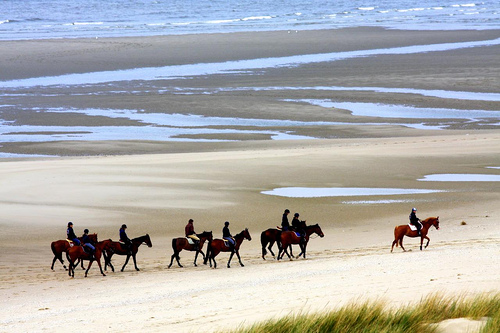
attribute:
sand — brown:
[0, 25, 499, 331]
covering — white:
[405, 220, 425, 235]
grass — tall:
[244, 301, 499, 326]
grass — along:
[244, 289, 491, 331]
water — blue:
[105, 7, 259, 38]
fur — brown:
[63, 238, 113, 278]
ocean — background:
[5, 2, 499, 36]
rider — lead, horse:
[410, 206, 422, 226]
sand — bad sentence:
[210, 257, 295, 331]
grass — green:
[298, 291, 438, 331]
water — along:
[269, 184, 399, 208]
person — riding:
[63, 220, 78, 245]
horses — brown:
[98, 206, 380, 263]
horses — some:
[231, 198, 353, 277]